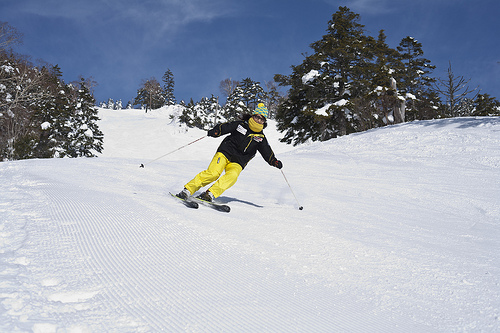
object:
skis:
[192, 191, 231, 211]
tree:
[306, 8, 412, 130]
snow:
[309, 103, 342, 125]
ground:
[66, 189, 165, 294]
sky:
[158, 9, 270, 79]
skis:
[168, 186, 198, 208]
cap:
[248, 100, 269, 118]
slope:
[0, 98, 493, 325]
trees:
[0, 30, 64, 159]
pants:
[187, 151, 247, 196]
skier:
[174, 100, 282, 200]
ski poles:
[140, 133, 208, 164]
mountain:
[4, 112, 498, 318]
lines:
[184, 255, 244, 329]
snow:
[3, 88, 496, 330]